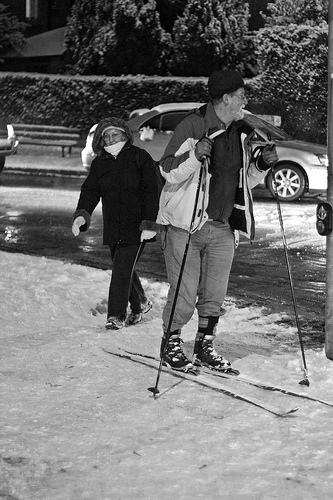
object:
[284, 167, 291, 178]
spoke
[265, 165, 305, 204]
rim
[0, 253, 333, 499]
snow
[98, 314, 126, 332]
shoe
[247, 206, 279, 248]
bad sentance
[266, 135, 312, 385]
hooker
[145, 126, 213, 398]
hooker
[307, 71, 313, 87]
leaf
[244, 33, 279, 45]
leaf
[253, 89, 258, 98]
leaf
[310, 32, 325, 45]
leaf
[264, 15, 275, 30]
leaf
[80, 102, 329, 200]
car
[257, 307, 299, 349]
snow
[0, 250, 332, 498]
ground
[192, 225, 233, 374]
leg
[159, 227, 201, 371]
leg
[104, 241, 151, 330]
leg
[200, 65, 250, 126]
person's head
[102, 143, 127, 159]
mask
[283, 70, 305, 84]
leaf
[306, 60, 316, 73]
leaf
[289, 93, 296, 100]
leaf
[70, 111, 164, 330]
person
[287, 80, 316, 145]
leaf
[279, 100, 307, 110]
leaf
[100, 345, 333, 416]
ski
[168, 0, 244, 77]
trees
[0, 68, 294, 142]
fence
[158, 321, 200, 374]
shoe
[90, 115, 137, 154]
head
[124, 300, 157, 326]
shoe